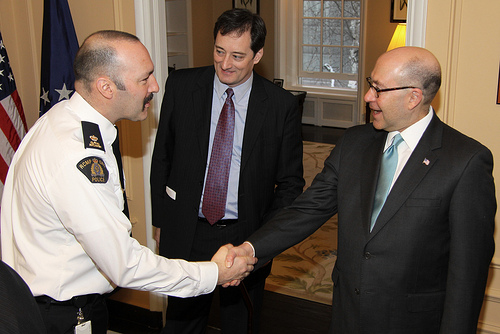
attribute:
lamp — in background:
[386, 23, 411, 50]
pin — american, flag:
[418, 155, 431, 172]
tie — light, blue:
[374, 131, 394, 241]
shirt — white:
[0, 92, 217, 301]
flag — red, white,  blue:
[36, 10, 76, 98]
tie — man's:
[199, 85, 238, 218]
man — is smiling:
[349, 39, 441, 137]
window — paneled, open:
[289, 1, 365, 96]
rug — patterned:
[257, 113, 370, 308]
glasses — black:
[358, 72, 421, 102]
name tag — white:
[64, 306, 99, 332]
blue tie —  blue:
[368, 134, 402, 232]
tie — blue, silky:
[354, 132, 407, 229]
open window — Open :
[279, 1, 366, 102]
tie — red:
[200, 84, 243, 226]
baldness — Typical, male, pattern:
[75, 24, 148, 72]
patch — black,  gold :
[74, 155, 114, 186]